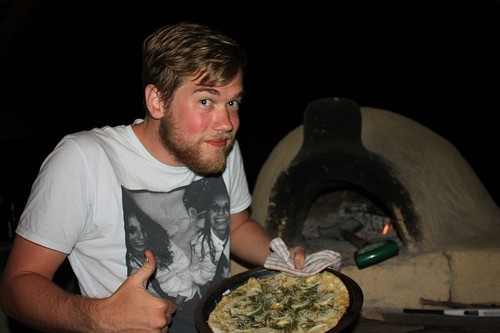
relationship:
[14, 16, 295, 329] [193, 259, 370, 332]
man holds plate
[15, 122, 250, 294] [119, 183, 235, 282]
shirt has photo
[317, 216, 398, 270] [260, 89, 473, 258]
shovel inside oven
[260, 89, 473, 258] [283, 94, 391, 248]
oven has opening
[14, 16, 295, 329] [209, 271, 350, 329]
man holds pizza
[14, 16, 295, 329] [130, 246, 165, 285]
man holds up thumb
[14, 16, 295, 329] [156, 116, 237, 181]
man has beard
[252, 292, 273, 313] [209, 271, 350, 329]
toppings are on pizza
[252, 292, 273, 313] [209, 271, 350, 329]
toppings are on top of pizza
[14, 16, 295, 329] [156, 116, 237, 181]
man has a beard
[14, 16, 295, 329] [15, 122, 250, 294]
man wears shirt